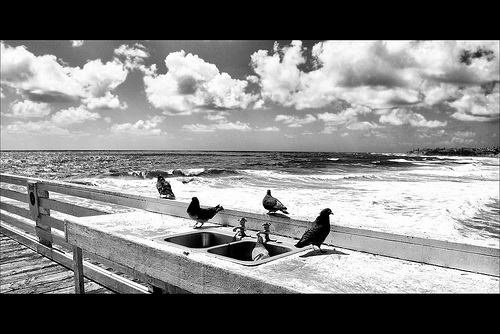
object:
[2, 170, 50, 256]
railings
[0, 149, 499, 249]
ocean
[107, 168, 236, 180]
wave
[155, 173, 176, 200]
bird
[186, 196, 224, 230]
bird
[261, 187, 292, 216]
bird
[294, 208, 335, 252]
bird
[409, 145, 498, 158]
land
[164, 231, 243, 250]
sink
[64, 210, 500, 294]
wood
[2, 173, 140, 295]
boardwalk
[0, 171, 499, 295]
fence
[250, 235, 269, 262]
bird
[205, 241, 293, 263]
sink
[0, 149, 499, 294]
water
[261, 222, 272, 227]
handle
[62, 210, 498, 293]
counter area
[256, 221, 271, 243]
faucet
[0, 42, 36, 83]
clouds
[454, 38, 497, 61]
clouds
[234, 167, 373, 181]
waves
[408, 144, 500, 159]
rocky area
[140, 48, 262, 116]
cloud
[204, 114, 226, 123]
cloud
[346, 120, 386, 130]
cloud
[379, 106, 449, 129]
cloud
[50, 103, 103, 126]
cloud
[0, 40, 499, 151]
sky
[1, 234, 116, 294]
deck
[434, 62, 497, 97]
cloud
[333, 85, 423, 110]
cloud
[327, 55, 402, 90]
cloud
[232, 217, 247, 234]
faucet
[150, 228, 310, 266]
double sink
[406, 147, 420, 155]
buildings